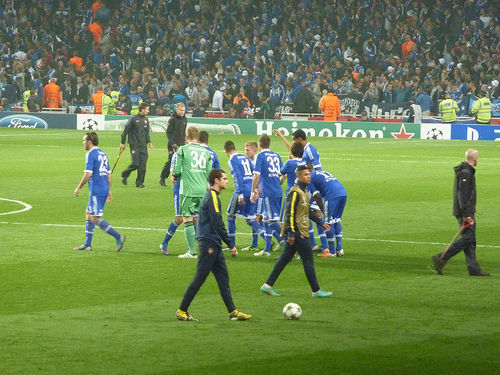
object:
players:
[74, 125, 354, 324]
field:
[0, 139, 500, 374]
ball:
[283, 302, 303, 320]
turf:
[8, 128, 78, 240]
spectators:
[6, 1, 497, 108]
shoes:
[311, 289, 333, 298]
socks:
[84, 219, 94, 247]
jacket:
[453, 162, 477, 218]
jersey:
[171, 142, 212, 195]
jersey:
[84, 146, 113, 196]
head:
[465, 149, 478, 166]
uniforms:
[227, 144, 352, 261]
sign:
[111, 114, 421, 139]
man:
[429, 146, 491, 277]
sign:
[1, 114, 75, 128]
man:
[261, 165, 332, 298]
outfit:
[266, 184, 323, 292]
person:
[317, 90, 340, 124]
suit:
[316, 94, 342, 119]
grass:
[0, 137, 500, 372]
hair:
[296, 165, 313, 172]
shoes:
[228, 309, 254, 321]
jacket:
[102, 94, 114, 114]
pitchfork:
[424, 218, 471, 276]